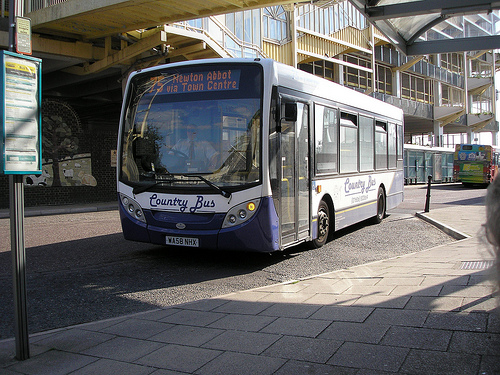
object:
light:
[247, 199, 256, 213]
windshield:
[120, 98, 265, 186]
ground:
[377, 247, 418, 309]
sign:
[2, 52, 43, 175]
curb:
[334, 275, 459, 338]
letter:
[149, 192, 160, 207]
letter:
[188, 194, 203, 213]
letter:
[180, 198, 191, 214]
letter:
[209, 199, 216, 208]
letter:
[170, 198, 178, 206]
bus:
[116, 57, 403, 255]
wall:
[0, 79, 117, 204]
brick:
[45, 109, 92, 146]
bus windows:
[313, 101, 338, 176]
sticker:
[16, 15, 32, 56]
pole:
[11, 182, 30, 361]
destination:
[146, 68, 238, 92]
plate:
[165, 236, 199, 248]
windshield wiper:
[145, 172, 231, 198]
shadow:
[0, 229, 496, 372]